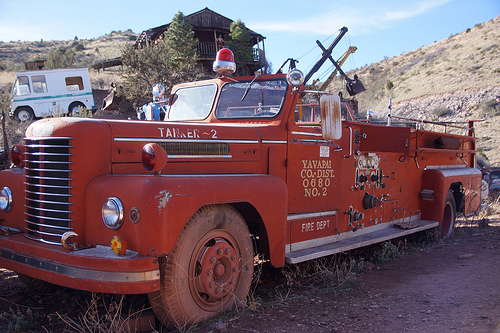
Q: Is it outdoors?
A: Yes, it is outdoors.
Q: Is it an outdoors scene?
A: Yes, it is outdoors.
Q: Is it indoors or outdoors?
A: It is outdoors.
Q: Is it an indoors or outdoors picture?
A: It is outdoors.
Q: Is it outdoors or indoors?
A: It is outdoors.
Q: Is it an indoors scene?
A: No, it is outdoors.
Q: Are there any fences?
A: No, there are no fences.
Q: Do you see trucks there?
A: Yes, there is a truck.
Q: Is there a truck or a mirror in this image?
A: Yes, there is a truck.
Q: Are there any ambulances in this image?
A: No, there are no ambulances.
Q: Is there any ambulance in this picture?
A: No, there are no ambulances.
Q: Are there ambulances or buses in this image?
A: No, there are no ambulances or buses.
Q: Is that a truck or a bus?
A: That is a truck.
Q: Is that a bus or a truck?
A: That is a truck.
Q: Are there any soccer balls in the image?
A: No, there are no soccer balls.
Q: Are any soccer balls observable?
A: No, there are no soccer balls.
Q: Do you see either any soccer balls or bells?
A: No, there are no soccer balls or bells.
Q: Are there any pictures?
A: No, there are no pictures.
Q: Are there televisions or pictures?
A: No, there are no pictures or televisions.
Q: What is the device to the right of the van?
A: The device is a screen.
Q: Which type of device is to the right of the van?
A: The device is a screen.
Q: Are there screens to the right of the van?
A: Yes, there is a screen to the right of the van.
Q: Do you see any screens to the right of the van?
A: Yes, there is a screen to the right of the van.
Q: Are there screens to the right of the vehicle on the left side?
A: Yes, there is a screen to the right of the van.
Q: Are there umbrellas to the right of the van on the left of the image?
A: No, there is a screen to the right of the van.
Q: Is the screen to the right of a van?
A: Yes, the screen is to the right of a van.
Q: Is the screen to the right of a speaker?
A: No, the screen is to the right of a van.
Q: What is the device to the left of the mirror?
A: The device is a screen.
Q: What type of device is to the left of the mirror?
A: The device is a screen.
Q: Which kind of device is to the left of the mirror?
A: The device is a screen.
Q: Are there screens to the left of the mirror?
A: Yes, there is a screen to the left of the mirror.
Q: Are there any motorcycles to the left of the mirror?
A: No, there is a screen to the left of the mirror.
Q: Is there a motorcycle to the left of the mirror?
A: No, there is a screen to the left of the mirror.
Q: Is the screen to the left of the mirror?
A: Yes, the screen is to the left of the mirror.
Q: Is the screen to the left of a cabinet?
A: No, the screen is to the left of the mirror.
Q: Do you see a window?
A: Yes, there is a window.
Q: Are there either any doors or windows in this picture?
A: Yes, there is a window.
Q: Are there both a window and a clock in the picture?
A: No, there is a window but no clocks.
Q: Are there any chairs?
A: No, there are no chairs.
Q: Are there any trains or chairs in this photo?
A: No, there are no chairs or trains.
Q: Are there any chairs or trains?
A: No, there are no chairs or trains.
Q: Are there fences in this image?
A: No, there are no fences.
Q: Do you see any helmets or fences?
A: No, there are no fences or helmets.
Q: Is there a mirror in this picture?
A: Yes, there is a mirror.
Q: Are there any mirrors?
A: Yes, there is a mirror.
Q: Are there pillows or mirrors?
A: Yes, there is a mirror.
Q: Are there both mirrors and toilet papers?
A: No, there is a mirror but no toilet papers.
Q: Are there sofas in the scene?
A: No, there are no sofas.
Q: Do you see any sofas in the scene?
A: No, there are no sofas.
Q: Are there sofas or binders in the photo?
A: No, there are no sofas or binders.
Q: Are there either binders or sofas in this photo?
A: No, there are no sofas or binders.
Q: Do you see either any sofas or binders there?
A: No, there are no sofas or binders.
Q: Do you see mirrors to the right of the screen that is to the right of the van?
A: Yes, there is a mirror to the right of the screen.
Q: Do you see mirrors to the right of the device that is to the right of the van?
A: Yes, there is a mirror to the right of the screen.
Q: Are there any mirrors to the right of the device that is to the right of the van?
A: Yes, there is a mirror to the right of the screen.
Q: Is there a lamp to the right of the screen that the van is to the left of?
A: No, there is a mirror to the right of the screen.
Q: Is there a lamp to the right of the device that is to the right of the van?
A: No, there is a mirror to the right of the screen.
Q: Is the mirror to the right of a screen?
A: Yes, the mirror is to the right of a screen.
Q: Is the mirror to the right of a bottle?
A: No, the mirror is to the right of a screen.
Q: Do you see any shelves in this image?
A: No, there are no shelves.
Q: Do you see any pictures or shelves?
A: No, there are no shelves or pictures.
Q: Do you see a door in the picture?
A: Yes, there is a door.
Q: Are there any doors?
A: Yes, there is a door.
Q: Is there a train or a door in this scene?
A: Yes, there is a door.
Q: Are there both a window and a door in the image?
A: Yes, there are both a door and a window.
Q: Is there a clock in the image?
A: No, there are no clocks.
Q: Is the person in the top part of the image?
A: Yes, the person is in the top of the image.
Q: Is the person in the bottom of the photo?
A: No, the person is in the top of the image.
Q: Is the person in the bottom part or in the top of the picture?
A: The person is in the top of the image.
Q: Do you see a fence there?
A: No, there are no fences.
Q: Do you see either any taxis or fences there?
A: No, there are no fences or taxis.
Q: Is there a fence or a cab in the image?
A: No, there are no fences or taxis.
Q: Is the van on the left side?
A: Yes, the van is on the left of the image.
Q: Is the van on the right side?
A: No, the van is on the left of the image.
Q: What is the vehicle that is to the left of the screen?
A: The vehicle is a van.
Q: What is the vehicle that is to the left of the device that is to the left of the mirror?
A: The vehicle is a van.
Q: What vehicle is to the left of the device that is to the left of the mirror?
A: The vehicle is a van.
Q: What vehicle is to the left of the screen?
A: The vehicle is a van.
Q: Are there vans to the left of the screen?
A: Yes, there is a van to the left of the screen.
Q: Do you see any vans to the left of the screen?
A: Yes, there is a van to the left of the screen.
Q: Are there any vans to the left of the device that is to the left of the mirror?
A: Yes, there is a van to the left of the screen.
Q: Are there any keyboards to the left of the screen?
A: No, there is a van to the left of the screen.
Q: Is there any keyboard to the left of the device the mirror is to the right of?
A: No, there is a van to the left of the screen.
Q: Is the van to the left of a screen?
A: Yes, the van is to the left of a screen.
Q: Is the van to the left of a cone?
A: No, the van is to the left of a screen.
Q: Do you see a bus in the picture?
A: No, there are no buses.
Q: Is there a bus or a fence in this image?
A: No, there are no buses or fences.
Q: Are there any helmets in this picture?
A: No, there are no helmets.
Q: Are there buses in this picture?
A: No, there are no buses.